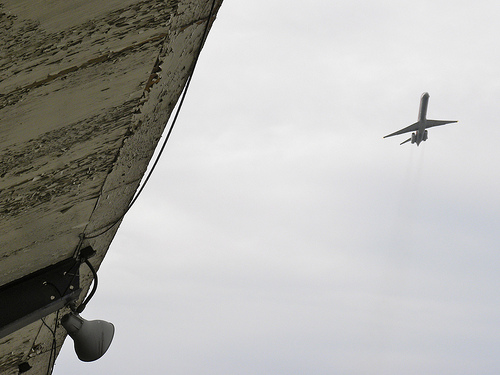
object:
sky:
[49, 0, 498, 374]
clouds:
[296, 210, 347, 253]